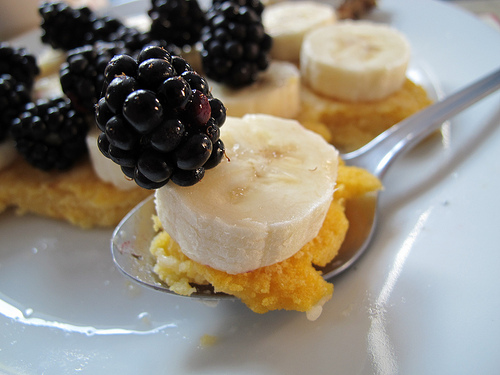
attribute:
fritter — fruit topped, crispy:
[157, 233, 355, 314]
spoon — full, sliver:
[110, 50, 498, 302]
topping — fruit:
[2, 3, 415, 260]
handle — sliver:
[350, 67, 498, 195]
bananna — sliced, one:
[155, 112, 345, 276]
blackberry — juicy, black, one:
[96, 50, 224, 188]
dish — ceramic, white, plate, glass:
[6, 1, 498, 372]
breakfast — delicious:
[5, 3, 440, 294]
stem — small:
[220, 147, 232, 164]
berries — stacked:
[4, 3, 261, 178]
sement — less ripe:
[192, 95, 214, 121]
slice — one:
[157, 109, 342, 272]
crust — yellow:
[140, 162, 386, 325]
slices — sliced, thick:
[262, 3, 421, 93]